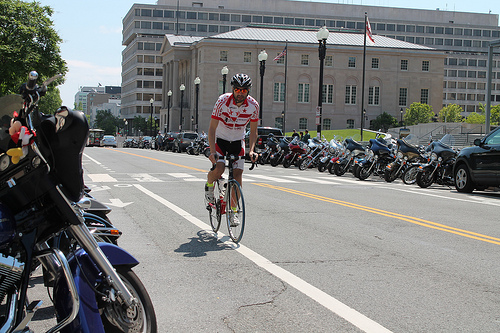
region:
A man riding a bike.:
[192, 70, 262, 242]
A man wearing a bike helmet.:
[225, 70, 250, 95]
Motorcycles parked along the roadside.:
[145, 95, 460, 187]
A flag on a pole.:
[355, 5, 375, 150]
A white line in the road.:
[77, 140, 409, 332]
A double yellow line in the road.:
[95, 140, 496, 251]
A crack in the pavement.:
[167, 250, 378, 330]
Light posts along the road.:
[145, 25, 330, 150]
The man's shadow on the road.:
[142, 215, 243, 271]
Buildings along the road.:
[75, 0, 496, 157]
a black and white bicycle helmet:
[229, 72, 253, 90]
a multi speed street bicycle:
[206, 149, 259, 244]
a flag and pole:
[359, 10, 376, 141]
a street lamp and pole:
[314, 23, 329, 142]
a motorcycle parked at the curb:
[417, 133, 458, 189]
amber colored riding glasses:
[231, 85, 250, 97]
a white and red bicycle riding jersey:
[210, 90, 260, 142]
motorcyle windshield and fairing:
[432, 133, 455, 155]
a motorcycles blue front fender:
[53, 242, 137, 332]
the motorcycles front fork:
[56, 189, 140, 314]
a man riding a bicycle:
[175, 48, 280, 250]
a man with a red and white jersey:
[177, 59, 269, 258]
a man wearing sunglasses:
[186, 41, 270, 253]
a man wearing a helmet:
[184, 35, 275, 261]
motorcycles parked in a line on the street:
[289, 129, 452, 192]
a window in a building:
[391, 76, 415, 111]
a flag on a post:
[351, 8, 379, 140]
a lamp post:
[309, 22, 330, 137]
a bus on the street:
[85, 113, 105, 153]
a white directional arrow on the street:
[101, 192, 136, 212]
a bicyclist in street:
[201, 73, 261, 249]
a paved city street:
[79, 146, 499, 331]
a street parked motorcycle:
[3, 74, 156, 331]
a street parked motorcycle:
[414, 134, 460, 186]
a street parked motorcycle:
[383, 132, 426, 184]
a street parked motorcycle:
[354, 130, 403, 177]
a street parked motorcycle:
[334, 137, 367, 174]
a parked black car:
[454, 131, 499, 195]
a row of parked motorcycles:
[186, 128, 449, 185]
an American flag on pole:
[360, 11, 376, 138]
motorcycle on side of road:
[415, 143, 450, 188]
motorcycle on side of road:
[390, 135, 420, 175]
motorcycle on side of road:
[331, 138, 356, 168]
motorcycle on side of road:
[306, 145, 323, 171]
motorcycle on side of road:
[303, 146, 318, 166]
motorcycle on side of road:
[283, 140, 300, 162]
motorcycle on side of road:
[273, 145, 285, 164]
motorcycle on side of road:
[266, 146, 278, 163]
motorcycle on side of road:
[0, 165, 148, 325]